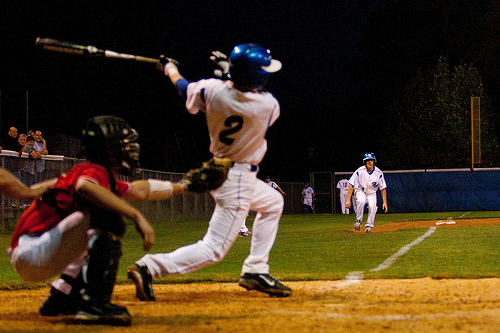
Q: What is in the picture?
A: Baseball players.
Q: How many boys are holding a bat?
A: One.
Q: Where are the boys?
A: Baseball field.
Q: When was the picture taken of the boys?
A: Nighttime.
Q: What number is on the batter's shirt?
A: Two.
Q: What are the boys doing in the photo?
A: Playing baseball.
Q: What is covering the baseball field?
A: Grass.